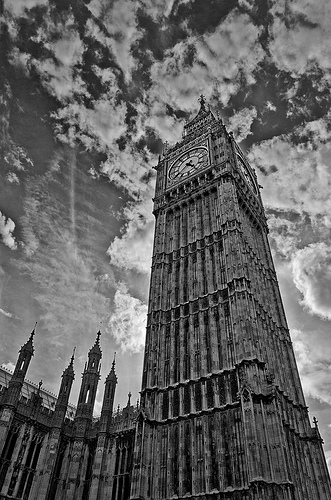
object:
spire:
[88, 345, 102, 354]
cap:
[86, 329, 103, 358]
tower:
[74, 329, 102, 423]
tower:
[129, 86, 331, 500]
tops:
[4, 321, 119, 390]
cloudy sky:
[0, 0, 331, 408]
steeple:
[181, 92, 226, 142]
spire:
[199, 93, 208, 115]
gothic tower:
[147, 94, 265, 313]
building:
[0, 321, 331, 497]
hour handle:
[185, 162, 194, 167]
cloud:
[195, 36, 254, 82]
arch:
[211, 185, 217, 195]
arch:
[203, 191, 210, 197]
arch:
[167, 208, 173, 215]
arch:
[174, 204, 180, 211]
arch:
[189, 198, 195, 205]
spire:
[197, 93, 212, 115]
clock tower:
[131, 92, 331, 475]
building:
[1, 94, 330, 498]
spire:
[7, 321, 37, 410]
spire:
[53, 346, 77, 429]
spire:
[73, 321, 102, 434]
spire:
[99, 351, 118, 436]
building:
[128, 92, 328, 499]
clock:
[167, 145, 209, 181]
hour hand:
[186, 163, 195, 166]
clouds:
[272, 176, 330, 214]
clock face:
[236, 151, 259, 198]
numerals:
[169, 148, 209, 181]